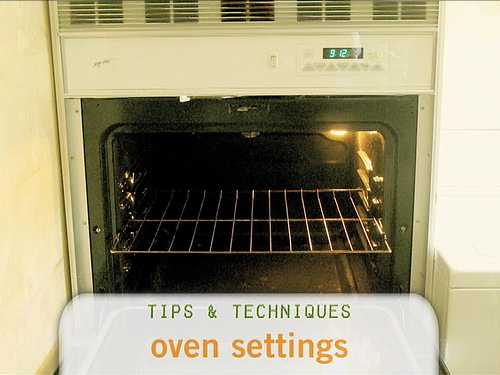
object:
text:
[147, 303, 351, 363]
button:
[347, 62, 363, 72]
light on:
[328, 129, 348, 137]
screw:
[400, 225, 409, 234]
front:
[58, 99, 433, 296]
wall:
[432, 0, 500, 375]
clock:
[319, 43, 366, 60]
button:
[300, 62, 316, 73]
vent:
[56, 0, 433, 24]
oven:
[46, 1, 448, 293]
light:
[326, 126, 347, 136]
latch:
[231, 103, 258, 112]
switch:
[268, 53, 278, 70]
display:
[321, 47, 365, 58]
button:
[312, 59, 329, 75]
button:
[324, 61, 339, 72]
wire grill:
[108, 187, 393, 253]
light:
[235, 128, 262, 145]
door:
[65, 35, 427, 300]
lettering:
[135, 330, 350, 367]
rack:
[111, 183, 397, 258]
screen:
[336, 304, 356, 319]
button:
[370, 61, 386, 71]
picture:
[0, 1, 500, 375]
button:
[337, 62, 351, 72]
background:
[58, 288, 443, 373]